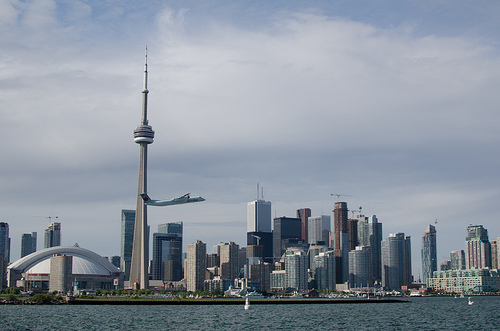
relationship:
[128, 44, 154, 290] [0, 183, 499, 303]
space needle in skyline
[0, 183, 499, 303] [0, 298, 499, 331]
skyline next to lake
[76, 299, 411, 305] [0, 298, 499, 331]
pier next to lake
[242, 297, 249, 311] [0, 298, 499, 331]
buoy in lake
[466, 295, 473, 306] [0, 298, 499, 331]
buoy in lake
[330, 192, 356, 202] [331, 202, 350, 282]
crane on top of building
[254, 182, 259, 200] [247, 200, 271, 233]
spire on top of building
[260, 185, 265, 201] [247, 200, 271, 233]
spire on top of building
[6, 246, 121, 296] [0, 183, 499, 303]
building in skyline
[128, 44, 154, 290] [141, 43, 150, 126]
space needle has spire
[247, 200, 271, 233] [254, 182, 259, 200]
building has spire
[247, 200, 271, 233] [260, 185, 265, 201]
building has spire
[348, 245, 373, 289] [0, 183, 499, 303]
building in skyline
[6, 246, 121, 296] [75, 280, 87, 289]
building has window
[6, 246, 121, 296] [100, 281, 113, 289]
building has window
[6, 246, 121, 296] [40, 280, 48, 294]
building has window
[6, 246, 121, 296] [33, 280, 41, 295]
building has window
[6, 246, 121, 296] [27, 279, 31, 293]
building has window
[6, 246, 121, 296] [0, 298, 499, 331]
building near lake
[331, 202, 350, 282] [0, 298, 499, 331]
building near lake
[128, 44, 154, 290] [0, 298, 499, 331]
space needle near lake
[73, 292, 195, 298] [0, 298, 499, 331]
grass near lake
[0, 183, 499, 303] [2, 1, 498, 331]
skyline in city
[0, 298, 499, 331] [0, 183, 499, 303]
lake in front of skyline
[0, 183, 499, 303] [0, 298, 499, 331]
skyline behind lake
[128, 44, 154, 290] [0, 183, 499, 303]
space needle taller than skyline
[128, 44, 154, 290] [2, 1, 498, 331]
space needle in city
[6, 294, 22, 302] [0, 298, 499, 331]
bush next to lake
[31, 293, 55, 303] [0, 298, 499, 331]
bush next to lake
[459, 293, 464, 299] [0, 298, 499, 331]
boat in lake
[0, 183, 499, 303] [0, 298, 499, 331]
skyline near lake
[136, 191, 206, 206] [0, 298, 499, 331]
plane above lake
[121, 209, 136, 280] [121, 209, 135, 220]
building has top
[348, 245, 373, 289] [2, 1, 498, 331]
building in city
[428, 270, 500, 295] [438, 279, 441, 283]
building has window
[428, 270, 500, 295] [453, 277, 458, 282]
building has window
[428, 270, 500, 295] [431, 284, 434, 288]
building has window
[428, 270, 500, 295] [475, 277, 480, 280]
building has window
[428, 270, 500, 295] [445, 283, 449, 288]
building has window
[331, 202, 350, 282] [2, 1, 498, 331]
building in city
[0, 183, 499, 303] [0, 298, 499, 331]
skyline near to lake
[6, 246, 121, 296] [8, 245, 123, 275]
building has roof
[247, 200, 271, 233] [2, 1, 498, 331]
building in city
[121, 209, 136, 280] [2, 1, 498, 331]
building in city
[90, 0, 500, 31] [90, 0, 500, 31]
blue sky above blue sky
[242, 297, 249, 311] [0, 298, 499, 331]
buoy on lake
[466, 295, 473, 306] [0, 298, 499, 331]
buoy on lake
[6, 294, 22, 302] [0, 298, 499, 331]
bush beside lake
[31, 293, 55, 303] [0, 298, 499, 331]
bush beside lake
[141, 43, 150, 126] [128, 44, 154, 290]
spire on top of space needle